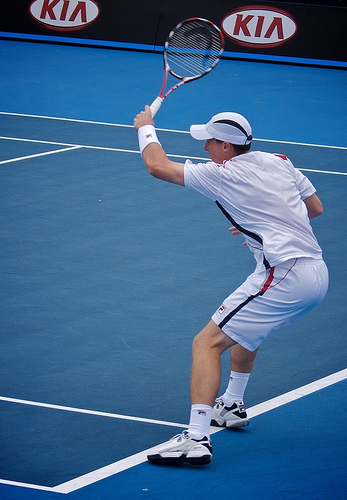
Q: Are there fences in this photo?
A: No, there are no fences.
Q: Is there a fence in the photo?
A: No, there are no fences.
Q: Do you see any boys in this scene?
A: No, there are no boys.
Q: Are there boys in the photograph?
A: No, there are no boys.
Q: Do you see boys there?
A: No, there are no boys.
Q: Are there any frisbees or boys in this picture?
A: No, there are no boys or frisbees.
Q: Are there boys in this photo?
A: No, there are no boys.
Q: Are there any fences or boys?
A: No, there are no boys or fences.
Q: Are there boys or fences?
A: No, there are no boys or fences.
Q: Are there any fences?
A: No, there are no fences.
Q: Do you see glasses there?
A: No, there are no glasses.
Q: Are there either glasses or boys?
A: No, there are no glasses or boys.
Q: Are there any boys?
A: No, there are no boys.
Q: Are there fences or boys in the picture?
A: No, there are no boys or fences.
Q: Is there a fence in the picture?
A: No, there are no fences.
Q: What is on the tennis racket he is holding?
A: The logo is on the racket.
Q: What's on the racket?
A: The logo is on the racket.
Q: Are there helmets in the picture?
A: No, there are no helmets.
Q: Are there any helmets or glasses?
A: No, there are no helmets or glasses.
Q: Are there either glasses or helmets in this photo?
A: No, there are no helmets or glasses.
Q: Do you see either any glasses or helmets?
A: No, there are no helmets or glasses.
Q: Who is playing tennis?
A: The man is playing tennis.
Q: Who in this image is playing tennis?
A: The man is playing tennis.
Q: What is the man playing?
A: The man is playing tennis.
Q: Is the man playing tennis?
A: Yes, the man is playing tennis.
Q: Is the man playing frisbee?
A: No, the man is playing tennis.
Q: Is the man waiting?
A: Yes, the man is waiting.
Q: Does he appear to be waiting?
A: Yes, the man is waiting.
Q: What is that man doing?
A: The man is waiting.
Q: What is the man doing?
A: The man is waiting.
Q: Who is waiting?
A: The man is waiting.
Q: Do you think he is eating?
A: No, the man is waiting.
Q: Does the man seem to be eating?
A: No, the man is waiting.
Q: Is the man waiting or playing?
A: The man is waiting.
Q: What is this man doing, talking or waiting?
A: The man is waiting.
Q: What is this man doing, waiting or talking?
A: The man is waiting.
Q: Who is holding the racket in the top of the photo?
A: The man is holding the racket.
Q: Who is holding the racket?
A: The man is holding the racket.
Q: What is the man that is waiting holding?
A: The man is holding the racket.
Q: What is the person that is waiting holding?
A: The man is holding the racket.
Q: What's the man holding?
A: The man is holding the racket.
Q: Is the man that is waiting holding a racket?
A: Yes, the man is holding a racket.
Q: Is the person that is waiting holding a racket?
A: Yes, the man is holding a racket.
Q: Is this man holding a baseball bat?
A: No, the man is holding a racket.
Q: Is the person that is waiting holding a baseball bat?
A: No, the man is holding a racket.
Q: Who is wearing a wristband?
A: The man is wearing a wristband.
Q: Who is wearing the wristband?
A: The man is wearing a wristband.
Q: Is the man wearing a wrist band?
A: Yes, the man is wearing a wrist band.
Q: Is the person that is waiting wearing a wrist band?
A: Yes, the man is wearing a wrist band.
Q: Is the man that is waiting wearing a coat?
A: No, the man is wearing a wrist band.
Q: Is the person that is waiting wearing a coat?
A: No, the man is wearing a wrist band.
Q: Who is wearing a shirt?
A: The man is wearing a shirt.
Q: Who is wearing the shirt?
A: The man is wearing a shirt.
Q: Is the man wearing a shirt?
A: Yes, the man is wearing a shirt.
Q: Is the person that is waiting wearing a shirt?
A: Yes, the man is wearing a shirt.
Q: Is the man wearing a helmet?
A: No, the man is wearing a shirt.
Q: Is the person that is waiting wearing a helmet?
A: No, the man is wearing a shirt.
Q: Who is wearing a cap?
A: The man is wearing a cap.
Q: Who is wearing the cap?
A: The man is wearing a cap.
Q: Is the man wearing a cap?
A: Yes, the man is wearing a cap.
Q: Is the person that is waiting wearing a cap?
A: Yes, the man is wearing a cap.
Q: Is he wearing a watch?
A: No, the man is wearing a cap.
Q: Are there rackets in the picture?
A: Yes, there is a racket.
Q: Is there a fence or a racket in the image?
A: Yes, there is a racket.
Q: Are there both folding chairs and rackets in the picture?
A: No, there is a racket but no folding chairs.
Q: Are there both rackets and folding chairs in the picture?
A: No, there is a racket but no folding chairs.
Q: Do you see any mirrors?
A: No, there are no mirrors.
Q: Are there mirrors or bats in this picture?
A: No, there are no mirrors or bats.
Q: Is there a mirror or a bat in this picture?
A: No, there are no mirrors or bats.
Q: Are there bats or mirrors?
A: No, there are no mirrors or bats.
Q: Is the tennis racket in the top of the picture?
A: Yes, the tennis racket is in the top of the image.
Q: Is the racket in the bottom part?
A: No, the racket is in the top of the image.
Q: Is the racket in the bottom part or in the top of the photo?
A: The racket is in the top of the image.